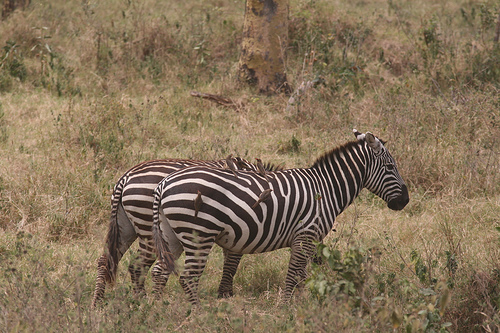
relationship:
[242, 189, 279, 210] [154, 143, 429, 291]
bird on zebra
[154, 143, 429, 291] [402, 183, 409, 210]
zebra has nose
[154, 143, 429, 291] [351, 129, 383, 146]
zebra has ears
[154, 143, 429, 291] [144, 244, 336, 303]
zebra has legs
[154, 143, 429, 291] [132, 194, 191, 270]
zebra has tail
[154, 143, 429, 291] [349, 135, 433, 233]
zebra has head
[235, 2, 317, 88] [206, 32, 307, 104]
tree has trunk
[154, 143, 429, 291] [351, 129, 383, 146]
zebra has ear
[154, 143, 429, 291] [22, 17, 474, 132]
zebra in field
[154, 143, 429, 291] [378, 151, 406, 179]
zebra has eye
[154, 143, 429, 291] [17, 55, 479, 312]
zebra in meadow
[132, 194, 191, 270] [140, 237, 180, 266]
tail has tuft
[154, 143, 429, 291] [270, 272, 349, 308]
zebra has feet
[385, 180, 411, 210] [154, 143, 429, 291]
nose on zebra